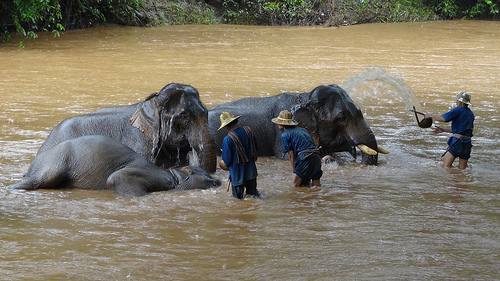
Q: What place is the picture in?
A: It is at the river.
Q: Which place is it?
A: It is a river.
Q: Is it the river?
A: Yes, it is the river.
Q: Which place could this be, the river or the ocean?
A: It is the river.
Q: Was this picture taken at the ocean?
A: No, the picture was taken in the river.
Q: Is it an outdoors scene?
A: Yes, it is outdoors.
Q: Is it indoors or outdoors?
A: It is outdoors.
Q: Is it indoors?
A: No, it is outdoors.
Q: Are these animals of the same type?
A: Yes, all the animals are elephants.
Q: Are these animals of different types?
A: No, all the animals are elephants.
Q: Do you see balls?
A: No, there are no balls.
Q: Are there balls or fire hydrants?
A: No, there are no balls or fire hydrants.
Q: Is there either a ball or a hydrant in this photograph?
A: No, there are no balls or fire hydrants.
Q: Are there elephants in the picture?
A: Yes, there is an elephant.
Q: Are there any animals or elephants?
A: Yes, there is an elephant.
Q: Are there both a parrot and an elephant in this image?
A: No, there is an elephant but no parrots.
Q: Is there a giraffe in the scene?
A: No, there are no giraffes.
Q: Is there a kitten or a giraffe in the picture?
A: No, there are no giraffes or kittens.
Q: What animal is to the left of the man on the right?
A: The animal is an elephant.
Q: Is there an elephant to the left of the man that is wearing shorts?
A: Yes, there is an elephant to the left of the man.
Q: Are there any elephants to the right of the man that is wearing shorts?
A: No, the elephant is to the left of the man.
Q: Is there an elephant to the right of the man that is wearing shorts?
A: No, the elephant is to the left of the man.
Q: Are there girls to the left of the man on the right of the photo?
A: No, there is an elephant to the left of the man.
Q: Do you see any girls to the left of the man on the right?
A: No, there is an elephant to the left of the man.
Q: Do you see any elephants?
A: Yes, there is an elephant.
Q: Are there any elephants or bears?
A: Yes, there is an elephant.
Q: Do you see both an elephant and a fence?
A: No, there is an elephant but no fences.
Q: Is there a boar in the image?
A: No, there are no boars.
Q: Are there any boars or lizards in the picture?
A: No, there are no boars or lizards.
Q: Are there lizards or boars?
A: No, there are no boars or lizards.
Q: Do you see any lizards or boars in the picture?
A: No, there are no boars or lizards.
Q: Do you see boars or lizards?
A: No, there are no boars or lizards.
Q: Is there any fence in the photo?
A: No, there are no fences.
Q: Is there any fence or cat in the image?
A: No, there are no fences or cats.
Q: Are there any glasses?
A: No, there are no glasses.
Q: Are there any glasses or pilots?
A: No, there are no glasses or pilots.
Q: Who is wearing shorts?
A: The man is wearing shorts.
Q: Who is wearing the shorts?
A: The man is wearing shorts.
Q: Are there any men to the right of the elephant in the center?
A: Yes, there is a man to the right of the elephant.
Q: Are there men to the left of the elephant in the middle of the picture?
A: No, the man is to the right of the elephant.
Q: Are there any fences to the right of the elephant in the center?
A: No, there is a man to the right of the elephant.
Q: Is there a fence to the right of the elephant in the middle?
A: No, there is a man to the right of the elephant.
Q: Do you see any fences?
A: No, there are no fences.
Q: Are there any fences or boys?
A: No, there are no fences or boys.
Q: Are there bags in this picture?
A: No, there are no bags.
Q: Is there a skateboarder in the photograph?
A: No, there are no skateboarders.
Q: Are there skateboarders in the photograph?
A: No, there are no skateboarders.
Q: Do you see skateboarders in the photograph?
A: No, there are no skateboarders.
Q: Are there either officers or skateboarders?
A: No, there are no skateboarders or officers.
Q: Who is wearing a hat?
A: The men are wearing a hat.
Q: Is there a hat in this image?
A: Yes, there is a hat.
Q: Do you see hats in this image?
A: Yes, there is a hat.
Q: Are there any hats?
A: Yes, there is a hat.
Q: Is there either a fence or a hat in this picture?
A: Yes, there is a hat.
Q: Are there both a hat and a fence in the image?
A: No, there is a hat but no fences.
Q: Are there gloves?
A: No, there are no gloves.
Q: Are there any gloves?
A: No, there are no gloves.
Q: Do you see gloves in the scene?
A: No, there are no gloves.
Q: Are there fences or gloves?
A: No, there are no gloves or fences.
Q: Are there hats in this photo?
A: Yes, there is a hat.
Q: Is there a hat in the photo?
A: Yes, there is a hat.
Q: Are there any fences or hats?
A: Yes, there is a hat.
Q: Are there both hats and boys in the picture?
A: No, there is a hat but no boys.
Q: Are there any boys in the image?
A: No, there are no boys.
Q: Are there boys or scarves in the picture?
A: No, there are no boys or scarves.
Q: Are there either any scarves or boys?
A: No, there are no boys or scarves.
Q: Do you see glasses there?
A: No, there are no glasses.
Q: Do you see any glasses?
A: No, there are no glasses.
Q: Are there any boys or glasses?
A: No, there are no glasses or boys.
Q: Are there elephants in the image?
A: Yes, there is an elephant.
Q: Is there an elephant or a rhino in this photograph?
A: Yes, there is an elephant.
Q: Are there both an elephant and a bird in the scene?
A: No, there is an elephant but no birds.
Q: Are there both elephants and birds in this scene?
A: No, there is an elephant but no birds.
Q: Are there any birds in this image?
A: No, there are no birds.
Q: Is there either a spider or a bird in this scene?
A: No, there are no birds or spiders.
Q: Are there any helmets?
A: No, there are no helmets.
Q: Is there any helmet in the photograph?
A: No, there are no helmets.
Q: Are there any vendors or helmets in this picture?
A: No, there are no helmets or vendors.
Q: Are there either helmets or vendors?
A: No, there are no helmets or vendors.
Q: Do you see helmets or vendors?
A: No, there are no helmets or vendors.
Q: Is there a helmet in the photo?
A: No, there are no helmets.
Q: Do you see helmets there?
A: No, there are no helmets.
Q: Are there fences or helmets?
A: No, there are no helmets or fences.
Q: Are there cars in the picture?
A: No, there are no cars.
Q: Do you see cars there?
A: No, there are no cars.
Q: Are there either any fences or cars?
A: No, there are no cars or fences.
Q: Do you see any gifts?
A: No, there are no gifts.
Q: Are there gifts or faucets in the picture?
A: No, there are no gifts or faucets.